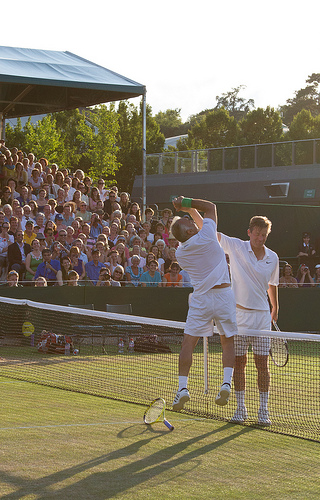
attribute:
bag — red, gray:
[37, 329, 80, 355]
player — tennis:
[220, 213, 287, 429]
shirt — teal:
[146, 259, 170, 277]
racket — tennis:
[266, 312, 292, 368]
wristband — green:
[180, 196, 192, 207]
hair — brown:
[245, 208, 275, 234]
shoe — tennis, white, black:
[171, 386, 189, 411]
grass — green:
[1, 341, 317, 497]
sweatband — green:
[179, 194, 194, 210]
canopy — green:
[0, 41, 148, 120]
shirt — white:
[215, 229, 297, 324]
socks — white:
[161, 348, 273, 396]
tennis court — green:
[19, 302, 301, 499]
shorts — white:
[226, 303, 283, 355]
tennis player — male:
[169, 188, 243, 417]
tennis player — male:
[170, 192, 282, 434]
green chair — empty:
[104, 302, 131, 314]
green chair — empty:
[65, 301, 96, 312]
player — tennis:
[223, 206, 315, 388]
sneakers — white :
[220, 397, 282, 431]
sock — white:
[178, 376, 189, 393]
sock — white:
[222, 365, 233, 382]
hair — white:
[130, 253, 141, 264]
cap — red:
[117, 336, 123, 341]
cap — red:
[129, 336, 134, 342]